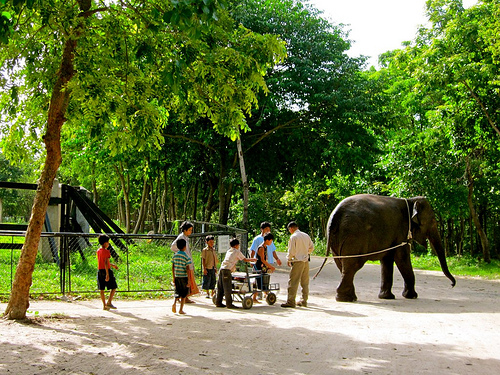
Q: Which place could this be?
A: It is a park.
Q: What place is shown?
A: It is a park.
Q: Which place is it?
A: It is a park.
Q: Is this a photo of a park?
A: Yes, it is showing a park.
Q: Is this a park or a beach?
A: It is a park.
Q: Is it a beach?
A: No, it is a park.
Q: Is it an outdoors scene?
A: Yes, it is outdoors.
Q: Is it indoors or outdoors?
A: It is outdoors.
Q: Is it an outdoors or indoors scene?
A: It is outdoors.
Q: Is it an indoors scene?
A: No, it is outdoors.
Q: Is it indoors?
A: No, it is outdoors.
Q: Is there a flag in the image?
A: No, there are no flags.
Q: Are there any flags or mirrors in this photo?
A: No, there are no flags or mirrors.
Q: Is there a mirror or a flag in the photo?
A: No, there are no flags or mirrors.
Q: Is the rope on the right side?
A: Yes, the rope is on the right of the image.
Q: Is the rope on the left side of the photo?
A: No, the rope is on the right of the image.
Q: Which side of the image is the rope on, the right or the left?
A: The rope is on the right of the image.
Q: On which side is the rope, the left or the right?
A: The rope is on the right of the image.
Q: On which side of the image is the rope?
A: The rope is on the right of the image.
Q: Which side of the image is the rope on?
A: The rope is on the right of the image.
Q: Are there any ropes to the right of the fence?
A: Yes, there is a rope to the right of the fence.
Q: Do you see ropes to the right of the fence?
A: Yes, there is a rope to the right of the fence.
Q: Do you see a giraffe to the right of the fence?
A: No, there is a rope to the right of the fence.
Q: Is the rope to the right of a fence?
A: Yes, the rope is to the right of a fence.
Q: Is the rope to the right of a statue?
A: No, the rope is to the right of a fence.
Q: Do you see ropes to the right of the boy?
A: Yes, there is a rope to the right of the boy.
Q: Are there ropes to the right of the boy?
A: Yes, there is a rope to the right of the boy.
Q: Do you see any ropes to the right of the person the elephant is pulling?
A: Yes, there is a rope to the right of the boy.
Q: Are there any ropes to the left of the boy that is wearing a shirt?
A: No, the rope is to the right of the boy.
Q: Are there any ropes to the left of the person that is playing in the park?
A: No, the rope is to the right of the boy.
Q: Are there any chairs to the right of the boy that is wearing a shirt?
A: No, there is a rope to the right of the boy.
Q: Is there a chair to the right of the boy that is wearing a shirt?
A: No, there is a rope to the right of the boy.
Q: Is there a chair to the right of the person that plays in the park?
A: No, there is a rope to the right of the boy.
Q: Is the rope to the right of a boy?
A: Yes, the rope is to the right of a boy.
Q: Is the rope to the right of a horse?
A: No, the rope is to the right of a boy.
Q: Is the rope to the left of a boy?
A: No, the rope is to the right of a boy.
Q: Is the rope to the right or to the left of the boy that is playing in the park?
A: The rope is to the right of the boy.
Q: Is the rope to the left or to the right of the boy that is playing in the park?
A: The rope is to the right of the boy.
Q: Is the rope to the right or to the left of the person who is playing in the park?
A: The rope is to the right of the boy.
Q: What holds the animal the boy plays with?
A: The rope holds the elephant.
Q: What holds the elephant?
A: The rope holds the elephant.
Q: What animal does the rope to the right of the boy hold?
A: The rope holds the elephant.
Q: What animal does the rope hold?
A: The rope holds the elephant.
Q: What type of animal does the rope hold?
A: The rope holds the elephant.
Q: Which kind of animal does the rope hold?
A: The rope holds the elephant.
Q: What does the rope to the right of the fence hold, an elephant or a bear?
A: The rope holds an elephant.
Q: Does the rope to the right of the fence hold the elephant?
A: Yes, the rope holds the elephant.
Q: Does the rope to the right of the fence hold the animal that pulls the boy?
A: Yes, the rope holds the elephant.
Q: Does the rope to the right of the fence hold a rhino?
A: No, the rope holds the elephant.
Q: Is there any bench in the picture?
A: No, there are no benches.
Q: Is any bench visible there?
A: No, there are no benches.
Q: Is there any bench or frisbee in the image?
A: No, there are no benches or frisbees.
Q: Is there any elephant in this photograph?
A: Yes, there is an elephant.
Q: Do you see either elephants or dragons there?
A: Yes, there is an elephant.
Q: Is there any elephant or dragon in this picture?
A: Yes, there is an elephant.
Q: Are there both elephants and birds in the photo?
A: No, there is an elephant but no birds.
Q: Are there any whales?
A: No, there are no whales.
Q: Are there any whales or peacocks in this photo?
A: No, there are no whales or peacocks.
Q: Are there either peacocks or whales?
A: No, there are no whales or peacocks.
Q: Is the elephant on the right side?
A: Yes, the elephant is on the right of the image.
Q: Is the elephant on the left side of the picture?
A: No, the elephant is on the right of the image.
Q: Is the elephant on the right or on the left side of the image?
A: The elephant is on the right of the image.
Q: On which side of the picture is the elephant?
A: The elephant is on the right of the image.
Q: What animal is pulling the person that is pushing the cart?
A: The elephant is pulling the boy.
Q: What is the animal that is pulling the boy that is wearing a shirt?
A: The animal is an elephant.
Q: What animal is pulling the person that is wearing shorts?
A: The animal is an elephant.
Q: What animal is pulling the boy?
A: The animal is an elephant.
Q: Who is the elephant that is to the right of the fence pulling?
A: The elephant is pulling the boy.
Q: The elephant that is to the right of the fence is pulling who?
A: The elephant is pulling the boy.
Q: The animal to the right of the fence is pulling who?
A: The elephant is pulling the boy.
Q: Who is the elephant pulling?
A: The elephant is pulling the boy.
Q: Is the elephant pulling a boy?
A: Yes, the elephant is pulling a boy.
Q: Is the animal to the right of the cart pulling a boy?
A: Yes, the elephant is pulling a boy.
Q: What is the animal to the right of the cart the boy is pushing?
A: The animal is an elephant.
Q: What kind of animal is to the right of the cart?
A: The animal is an elephant.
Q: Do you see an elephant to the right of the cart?
A: Yes, there is an elephant to the right of the cart.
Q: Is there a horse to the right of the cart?
A: No, there is an elephant to the right of the cart.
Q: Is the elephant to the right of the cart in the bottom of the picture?
A: Yes, the elephant is to the right of the cart.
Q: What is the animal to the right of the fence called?
A: The animal is an elephant.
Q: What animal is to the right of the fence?
A: The animal is an elephant.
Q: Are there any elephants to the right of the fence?
A: Yes, there is an elephant to the right of the fence.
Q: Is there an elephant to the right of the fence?
A: Yes, there is an elephant to the right of the fence.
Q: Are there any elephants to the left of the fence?
A: No, the elephant is to the right of the fence.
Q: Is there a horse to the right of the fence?
A: No, there is an elephant to the right of the fence.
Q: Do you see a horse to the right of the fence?
A: No, there is an elephant to the right of the fence.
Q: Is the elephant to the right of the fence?
A: Yes, the elephant is to the right of the fence.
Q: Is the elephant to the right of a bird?
A: No, the elephant is to the right of the fence.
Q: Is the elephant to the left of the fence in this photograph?
A: No, the elephant is to the right of the fence.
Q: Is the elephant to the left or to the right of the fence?
A: The elephant is to the right of the fence.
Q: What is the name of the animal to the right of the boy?
A: The animal is an elephant.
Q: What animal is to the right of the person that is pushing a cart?
A: The animal is an elephant.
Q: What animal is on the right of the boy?
A: The animal is an elephant.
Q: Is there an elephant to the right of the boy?
A: Yes, there is an elephant to the right of the boy.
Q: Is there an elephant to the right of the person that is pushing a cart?
A: Yes, there is an elephant to the right of the boy.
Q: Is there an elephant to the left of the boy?
A: No, the elephant is to the right of the boy.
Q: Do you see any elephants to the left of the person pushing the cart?
A: No, the elephant is to the right of the boy.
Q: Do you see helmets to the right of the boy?
A: No, there is an elephant to the right of the boy.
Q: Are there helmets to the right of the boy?
A: No, there is an elephant to the right of the boy.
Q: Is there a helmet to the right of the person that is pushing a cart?
A: No, there is an elephant to the right of the boy.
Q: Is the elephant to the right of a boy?
A: Yes, the elephant is to the right of a boy.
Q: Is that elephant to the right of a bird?
A: No, the elephant is to the right of a boy.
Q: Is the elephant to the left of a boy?
A: No, the elephant is to the right of a boy.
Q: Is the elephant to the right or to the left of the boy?
A: The elephant is to the right of the boy.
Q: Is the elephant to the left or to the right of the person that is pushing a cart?
A: The elephant is to the right of the boy.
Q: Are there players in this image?
A: No, there are no players.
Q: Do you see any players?
A: No, there are no players.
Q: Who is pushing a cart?
A: The boy is pushing a cart.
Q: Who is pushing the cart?
A: The boy is pushing a cart.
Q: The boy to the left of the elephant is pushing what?
A: The boy is pushing a cart.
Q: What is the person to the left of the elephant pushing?
A: The boy is pushing a cart.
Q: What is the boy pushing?
A: The boy is pushing a cart.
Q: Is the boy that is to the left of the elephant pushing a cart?
A: Yes, the boy is pushing a cart.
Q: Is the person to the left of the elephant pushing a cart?
A: Yes, the boy is pushing a cart.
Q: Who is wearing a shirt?
A: The boy is wearing a shirt.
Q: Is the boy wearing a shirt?
A: Yes, the boy is wearing a shirt.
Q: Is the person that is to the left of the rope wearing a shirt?
A: Yes, the boy is wearing a shirt.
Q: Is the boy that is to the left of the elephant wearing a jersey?
A: No, the boy is wearing a shirt.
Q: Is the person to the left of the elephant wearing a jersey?
A: No, the boy is wearing a shirt.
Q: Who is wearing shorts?
A: The boy is wearing shorts.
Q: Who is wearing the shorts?
A: The boy is wearing shorts.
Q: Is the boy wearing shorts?
A: Yes, the boy is wearing shorts.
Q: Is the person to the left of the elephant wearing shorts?
A: Yes, the boy is wearing shorts.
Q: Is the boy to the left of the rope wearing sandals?
A: No, the boy is wearing shorts.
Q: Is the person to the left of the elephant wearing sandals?
A: No, the boy is wearing shorts.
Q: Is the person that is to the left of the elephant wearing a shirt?
A: Yes, the boy is wearing a shirt.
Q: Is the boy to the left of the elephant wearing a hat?
A: No, the boy is wearing a shirt.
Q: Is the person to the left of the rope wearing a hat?
A: No, the boy is wearing a shirt.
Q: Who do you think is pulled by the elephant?
A: The boy is pulled by the elephant.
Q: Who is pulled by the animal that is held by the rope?
A: The boy is pulled by the elephant.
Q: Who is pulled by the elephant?
A: The boy is pulled by the elephant.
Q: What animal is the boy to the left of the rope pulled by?
A: The boy is pulled by the elephant.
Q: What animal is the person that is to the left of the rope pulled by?
A: The boy is pulled by the elephant.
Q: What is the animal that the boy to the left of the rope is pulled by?
A: The animal is an elephant.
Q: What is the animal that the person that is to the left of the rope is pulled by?
A: The animal is an elephant.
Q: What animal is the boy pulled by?
A: The boy is pulled by the elephant.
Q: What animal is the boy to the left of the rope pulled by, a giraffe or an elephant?
A: The boy is pulled by an elephant.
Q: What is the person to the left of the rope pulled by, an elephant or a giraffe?
A: The boy is pulled by an elephant.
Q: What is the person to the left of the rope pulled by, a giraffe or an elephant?
A: The boy is pulled by an elephant.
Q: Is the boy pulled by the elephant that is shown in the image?
A: Yes, the boy is pulled by the elephant.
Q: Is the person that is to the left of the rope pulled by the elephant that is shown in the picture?
A: Yes, the boy is pulled by the elephant.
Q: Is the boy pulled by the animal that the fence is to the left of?
A: Yes, the boy is pulled by the elephant.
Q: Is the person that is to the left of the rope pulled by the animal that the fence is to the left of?
A: Yes, the boy is pulled by the elephant.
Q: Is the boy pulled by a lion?
A: No, the boy is pulled by the elephant.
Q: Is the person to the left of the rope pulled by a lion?
A: No, the boy is pulled by the elephant.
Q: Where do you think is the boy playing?
A: The boy is playing in the park.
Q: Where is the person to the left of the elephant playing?
A: The boy is playing in the park.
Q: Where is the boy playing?
A: The boy is playing in the park.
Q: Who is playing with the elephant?
A: The boy is playing with the elephant.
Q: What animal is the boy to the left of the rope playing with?
A: The boy is playing with the elephant.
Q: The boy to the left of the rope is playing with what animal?
A: The boy is playing with the elephant.